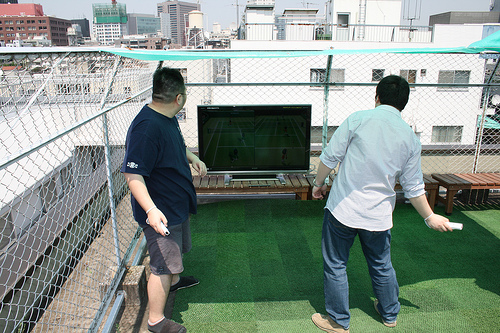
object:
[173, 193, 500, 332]
grass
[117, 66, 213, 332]
man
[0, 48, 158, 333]
fence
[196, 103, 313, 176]
television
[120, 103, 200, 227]
t-shirt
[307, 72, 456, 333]
man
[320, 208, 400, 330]
jeans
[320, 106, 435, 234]
shirt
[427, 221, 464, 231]
control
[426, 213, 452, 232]
hand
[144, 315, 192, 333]
shoes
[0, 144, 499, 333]
roof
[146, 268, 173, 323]
leg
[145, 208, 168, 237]
hand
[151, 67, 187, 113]
head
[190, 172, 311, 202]
bench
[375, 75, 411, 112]
hair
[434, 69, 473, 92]
window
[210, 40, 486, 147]
building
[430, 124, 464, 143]
window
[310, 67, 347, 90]
window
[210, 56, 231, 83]
window